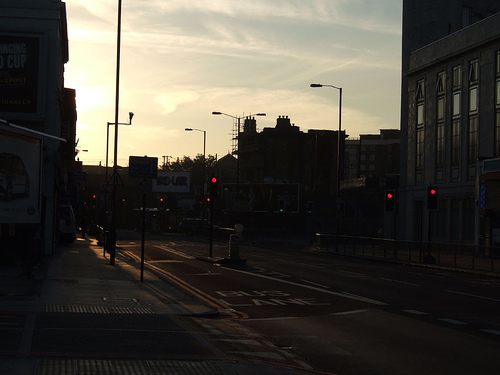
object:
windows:
[470, 90, 477, 113]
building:
[398, 1, 498, 287]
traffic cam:
[107, 111, 135, 257]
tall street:
[100, 105, 407, 345]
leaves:
[195, 156, 208, 166]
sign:
[155, 171, 191, 192]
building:
[128, 156, 158, 237]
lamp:
[207, 178, 220, 196]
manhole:
[47, 304, 151, 313]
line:
[162, 271, 214, 309]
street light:
[254, 114, 263, 118]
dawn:
[58, 8, 458, 268]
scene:
[6, 21, 417, 355]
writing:
[252, 297, 275, 305]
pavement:
[116, 227, 498, 372]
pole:
[109, 0, 123, 268]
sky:
[65, 0, 410, 166]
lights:
[309, 85, 323, 88]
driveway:
[0, 299, 310, 365]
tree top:
[169, 146, 227, 185]